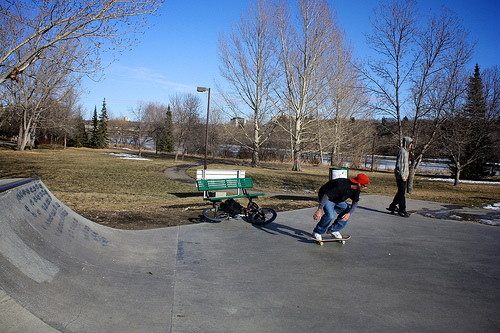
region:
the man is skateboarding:
[302, 163, 370, 253]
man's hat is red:
[350, 160, 372, 190]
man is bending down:
[315, 140, 363, 237]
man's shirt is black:
[315, 174, 355, 204]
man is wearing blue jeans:
[315, 198, 361, 239]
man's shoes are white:
[310, 222, 349, 244]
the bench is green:
[191, 172, 267, 199]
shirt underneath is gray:
[309, 188, 376, 217]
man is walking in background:
[390, 108, 432, 230]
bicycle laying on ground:
[200, 193, 277, 235]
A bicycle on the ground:
[199, 194, 279, 226]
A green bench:
[196, 174, 261, 204]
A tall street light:
[195, 79, 220, 173]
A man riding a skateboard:
[306, 170, 371, 247]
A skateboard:
[304, 230, 355, 246]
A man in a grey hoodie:
[381, 135, 431, 212]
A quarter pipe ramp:
[0, 177, 180, 332]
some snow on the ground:
[110, 148, 147, 165]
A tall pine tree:
[154, 104, 179, 157]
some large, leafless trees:
[212, 2, 358, 162]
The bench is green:
[167, 165, 278, 208]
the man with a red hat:
[332, 137, 389, 268]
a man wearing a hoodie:
[386, 121, 426, 261]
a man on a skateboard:
[293, 136, 373, 285]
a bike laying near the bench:
[172, 186, 315, 243]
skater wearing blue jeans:
[297, 180, 372, 257]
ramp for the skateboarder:
[4, 160, 174, 327]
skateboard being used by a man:
[293, 216, 369, 251]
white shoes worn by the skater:
[285, 212, 363, 249]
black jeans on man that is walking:
[382, 158, 432, 230]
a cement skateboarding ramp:
[0, 178, 492, 329]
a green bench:
[191, 170, 261, 200]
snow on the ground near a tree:
[105, 102, 155, 162]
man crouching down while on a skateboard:
[306, 170, 368, 245]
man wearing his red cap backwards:
[341, 170, 371, 195]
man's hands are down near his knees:
[310, 200, 360, 227]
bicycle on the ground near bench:
[196, 176, 277, 227]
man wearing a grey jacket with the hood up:
[389, 135, 417, 181]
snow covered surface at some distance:
[133, 130, 460, 168]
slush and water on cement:
[408, 193, 498, 228]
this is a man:
[311, 172, 372, 232]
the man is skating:
[311, 171, 369, 241]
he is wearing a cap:
[354, 172, 366, 180]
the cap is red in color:
[357, 173, 366, 181]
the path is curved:
[1, 187, 49, 288]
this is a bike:
[201, 195, 270, 224]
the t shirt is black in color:
[333, 181, 346, 196]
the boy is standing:
[383, 137, 415, 210]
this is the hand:
[314, 202, 324, 219]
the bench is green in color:
[212, 179, 234, 186]